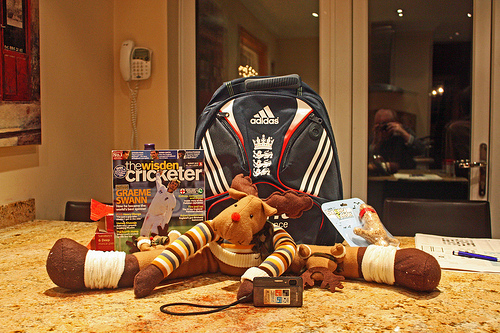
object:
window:
[193, 0, 490, 216]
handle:
[240, 73, 302, 92]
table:
[0, 292, 75, 333]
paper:
[412, 233, 499, 273]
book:
[110, 149, 205, 255]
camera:
[159, 276, 303, 316]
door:
[322, 0, 500, 203]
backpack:
[194, 73, 344, 246]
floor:
[36, 167, 78, 195]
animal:
[47, 173, 442, 303]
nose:
[231, 211, 241, 221]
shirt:
[151, 220, 297, 284]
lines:
[299, 128, 334, 197]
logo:
[250, 105, 280, 125]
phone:
[118, 39, 151, 150]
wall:
[40, 0, 150, 38]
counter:
[62, 310, 80, 319]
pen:
[452, 250, 500, 263]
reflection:
[193, 2, 319, 117]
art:
[0, 0, 41, 147]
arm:
[403, 125, 426, 156]